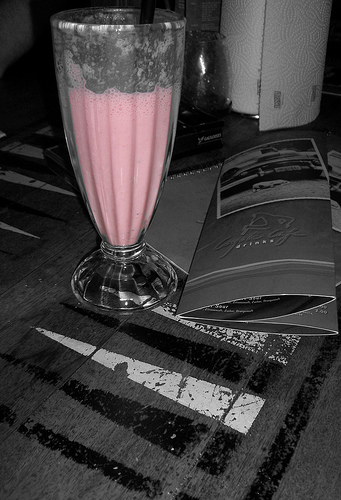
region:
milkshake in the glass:
[42, 57, 154, 244]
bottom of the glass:
[97, 254, 181, 310]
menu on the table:
[209, 135, 318, 352]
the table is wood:
[41, 359, 282, 489]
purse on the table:
[225, 7, 316, 123]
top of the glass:
[63, 7, 169, 31]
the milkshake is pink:
[106, 179, 134, 223]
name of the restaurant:
[227, 210, 300, 245]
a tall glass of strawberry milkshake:
[50, 7, 187, 313]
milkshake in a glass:
[67, 87, 175, 244]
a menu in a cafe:
[172, 137, 340, 333]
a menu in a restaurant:
[177, 136, 338, 336]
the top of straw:
[137, 2, 154, 23]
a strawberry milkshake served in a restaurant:
[50, 4, 187, 312]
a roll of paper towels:
[227, 0, 331, 132]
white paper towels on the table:
[225, 1, 332, 133]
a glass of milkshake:
[50, 1, 179, 313]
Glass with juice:
[49, 14, 197, 320]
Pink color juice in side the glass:
[48, 75, 172, 222]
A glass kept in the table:
[38, 10, 194, 311]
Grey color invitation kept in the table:
[180, 204, 330, 349]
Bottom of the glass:
[69, 244, 177, 310]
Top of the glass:
[43, 2, 192, 41]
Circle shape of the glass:
[38, 4, 192, 39]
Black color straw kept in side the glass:
[131, 1, 167, 32]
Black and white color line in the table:
[15, 318, 307, 496]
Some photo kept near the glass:
[221, 127, 322, 202]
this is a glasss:
[39, 12, 190, 311]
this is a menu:
[197, 136, 322, 330]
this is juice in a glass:
[73, 86, 161, 242]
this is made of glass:
[111, 118, 153, 183]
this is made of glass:
[115, 92, 178, 162]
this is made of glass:
[60, 74, 120, 129]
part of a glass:
[102, 114, 120, 140]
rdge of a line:
[235, 420, 250, 440]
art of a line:
[171, 463, 191, 494]